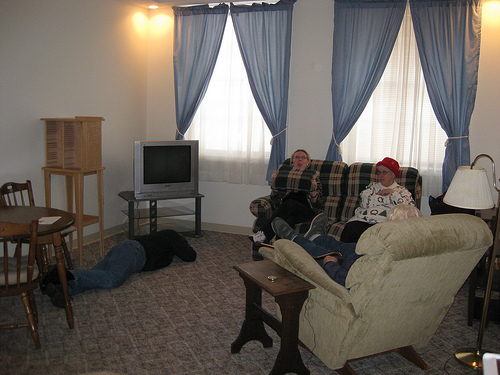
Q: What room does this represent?
A: It represents the living room.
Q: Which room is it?
A: It is a living room.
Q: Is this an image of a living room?
A: Yes, it is showing a living room.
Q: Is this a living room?
A: Yes, it is a living room.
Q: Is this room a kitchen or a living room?
A: It is a living room.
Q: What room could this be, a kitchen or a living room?
A: It is a living room.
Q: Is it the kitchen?
A: No, it is the living room.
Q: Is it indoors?
A: Yes, it is indoors.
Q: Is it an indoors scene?
A: Yes, it is indoors.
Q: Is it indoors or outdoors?
A: It is indoors.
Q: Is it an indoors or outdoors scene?
A: It is indoors.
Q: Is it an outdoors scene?
A: No, it is indoors.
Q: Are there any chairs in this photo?
A: Yes, there is a chair.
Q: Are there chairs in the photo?
A: Yes, there is a chair.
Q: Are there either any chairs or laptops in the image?
A: Yes, there is a chair.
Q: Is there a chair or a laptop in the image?
A: Yes, there is a chair.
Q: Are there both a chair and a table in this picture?
A: Yes, there are both a chair and a table.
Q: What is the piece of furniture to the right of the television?
A: The piece of furniture is a chair.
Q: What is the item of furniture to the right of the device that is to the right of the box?
A: The piece of furniture is a chair.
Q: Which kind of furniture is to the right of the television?
A: The piece of furniture is a chair.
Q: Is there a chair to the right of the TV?
A: Yes, there is a chair to the right of the TV.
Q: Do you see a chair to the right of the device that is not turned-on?
A: Yes, there is a chair to the right of the TV.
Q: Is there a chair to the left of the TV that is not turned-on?
A: No, the chair is to the right of the TV.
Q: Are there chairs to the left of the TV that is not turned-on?
A: No, the chair is to the right of the TV.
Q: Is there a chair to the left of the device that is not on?
A: No, the chair is to the right of the TV.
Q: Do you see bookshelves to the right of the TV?
A: No, there is a chair to the right of the TV.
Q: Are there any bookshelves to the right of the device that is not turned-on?
A: No, there is a chair to the right of the TV.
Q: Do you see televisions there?
A: Yes, there is a television.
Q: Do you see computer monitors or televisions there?
A: Yes, there is a television.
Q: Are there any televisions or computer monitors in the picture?
A: Yes, there is a television.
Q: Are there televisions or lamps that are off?
A: Yes, the television is off.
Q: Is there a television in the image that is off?
A: Yes, there is a television that is off.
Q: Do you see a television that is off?
A: Yes, there is a television that is off.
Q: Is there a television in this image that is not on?
A: Yes, there is a television that is off.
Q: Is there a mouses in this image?
A: No, there are no computer mousess.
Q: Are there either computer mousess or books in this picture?
A: No, there are no computer mousess or books.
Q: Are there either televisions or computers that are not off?
A: No, there is a television but it is off.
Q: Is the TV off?
A: Yes, the TV is off.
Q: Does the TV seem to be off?
A: Yes, the TV is off.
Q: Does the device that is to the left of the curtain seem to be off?
A: Yes, the TV is off.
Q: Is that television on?
A: No, the television is off.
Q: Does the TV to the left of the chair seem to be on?
A: No, the television is off.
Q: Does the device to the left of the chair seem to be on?
A: No, the television is off.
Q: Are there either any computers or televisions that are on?
A: No, there is a television but it is off.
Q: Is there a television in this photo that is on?
A: No, there is a television but it is off.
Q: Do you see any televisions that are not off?
A: No, there is a television but it is off.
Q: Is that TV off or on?
A: The TV is off.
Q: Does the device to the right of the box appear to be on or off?
A: The TV is off.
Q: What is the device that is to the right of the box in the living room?
A: The device is a television.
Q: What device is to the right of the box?
A: The device is a television.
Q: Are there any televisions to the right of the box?
A: Yes, there is a television to the right of the box.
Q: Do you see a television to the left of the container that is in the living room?
A: No, the television is to the right of the box.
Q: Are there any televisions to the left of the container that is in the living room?
A: No, the television is to the right of the box.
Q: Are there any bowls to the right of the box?
A: No, there is a television to the right of the box.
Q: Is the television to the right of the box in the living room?
A: Yes, the television is to the right of the box.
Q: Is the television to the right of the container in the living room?
A: Yes, the television is to the right of the box.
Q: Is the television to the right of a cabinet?
A: No, the television is to the right of the box.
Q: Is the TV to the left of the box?
A: No, the TV is to the right of the box.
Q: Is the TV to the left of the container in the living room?
A: No, the TV is to the right of the box.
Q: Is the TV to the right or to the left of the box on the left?
A: The TV is to the right of the box.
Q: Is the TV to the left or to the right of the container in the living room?
A: The TV is to the right of the box.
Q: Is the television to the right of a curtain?
A: No, the television is to the left of a curtain.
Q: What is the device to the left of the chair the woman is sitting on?
A: The device is a television.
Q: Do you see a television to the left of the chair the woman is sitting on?
A: Yes, there is a television to the left of the chair.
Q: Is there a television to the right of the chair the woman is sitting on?
A: No, the television is to the left of the chair.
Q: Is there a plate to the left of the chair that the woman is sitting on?
A: No, there is a television to the left of the chair.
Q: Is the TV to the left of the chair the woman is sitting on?
A: Yes, the TV is to the left of the chair.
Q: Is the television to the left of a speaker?
A: No, the television is to the left of the chair.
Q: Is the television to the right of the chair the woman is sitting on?
A: No, the television is to the left of the chair.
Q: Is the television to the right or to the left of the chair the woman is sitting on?
A: The television is to the left of the chair.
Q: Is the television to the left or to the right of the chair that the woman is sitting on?
A: The television is to the left of the chair.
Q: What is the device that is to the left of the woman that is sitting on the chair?
A: The device is a television.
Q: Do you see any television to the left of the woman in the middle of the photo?
A: Yes, there is a television to the left of the woman.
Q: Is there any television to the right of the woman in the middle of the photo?
A: No, the television is to the left of the woman.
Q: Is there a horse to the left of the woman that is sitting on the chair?
A: No, there is a television to the left of the woman.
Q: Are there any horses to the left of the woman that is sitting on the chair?
A: No, there is a television to the left of the woman.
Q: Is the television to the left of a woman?
A: Yes, the television is to the left of a woman.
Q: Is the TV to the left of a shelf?
A: No, the TV is to the left of a woman.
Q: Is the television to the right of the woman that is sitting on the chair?
A: No, the television is to the left of the woman.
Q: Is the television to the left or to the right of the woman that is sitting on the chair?
A: The television is to the left of the woman.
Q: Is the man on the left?
A: Yes, the man is on the left of the image.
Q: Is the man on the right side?
A: No, the man is on the left of the image.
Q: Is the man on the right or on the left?
A: The man is on the left of the image.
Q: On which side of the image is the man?
A: The man is on the left of the image.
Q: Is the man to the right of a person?
A: No, the man is to the left of a person.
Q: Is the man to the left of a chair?
A: No, the man is to the right of a chair.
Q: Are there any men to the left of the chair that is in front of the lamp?
A: Yes, there is a man to the left of the chair.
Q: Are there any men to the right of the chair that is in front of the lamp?
A: No, the man is to the left of the chair.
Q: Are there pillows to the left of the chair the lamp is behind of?
A: No, there is a man to the left of the chair.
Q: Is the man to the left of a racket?
A: No, the man is to the left of a chair.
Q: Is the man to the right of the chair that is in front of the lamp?
A: No, the man is to the left of the chair.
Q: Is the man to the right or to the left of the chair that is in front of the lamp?
A: The man is to the left of the chair.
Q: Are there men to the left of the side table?
A: Yes, there is a man to the left of the side table.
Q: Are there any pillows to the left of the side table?
A: No, there is a man to the left of the side table.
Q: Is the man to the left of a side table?
A: Yes, the man is to the left of a side table.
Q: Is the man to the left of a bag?
A: No, the man is to the left of a side table.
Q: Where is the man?
A: The man is on the floor.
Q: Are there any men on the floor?
A: Yes, there is a man on the floor.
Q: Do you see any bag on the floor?
A: No, there is a man on the floor.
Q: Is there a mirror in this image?
A: No, there are no mirrors.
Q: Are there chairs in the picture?
A: Yes, there is a chair.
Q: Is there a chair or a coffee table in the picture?
A: Yes, there is a chair.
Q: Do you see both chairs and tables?
A: Yes, there are both a chair and a table.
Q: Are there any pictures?
A: No, there are no pictures.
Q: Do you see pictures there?
A: No, there are no pictures.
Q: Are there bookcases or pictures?
A: No, there are no pictures or bookcases.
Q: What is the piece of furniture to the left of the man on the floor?
A: The piece of furniture is a chair.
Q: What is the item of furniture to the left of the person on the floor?
A: The piece of furniture is a chair.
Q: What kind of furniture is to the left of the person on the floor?
A: The piece of furniture is a chair.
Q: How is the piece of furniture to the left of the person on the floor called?
A: The piece of furniture is a chair.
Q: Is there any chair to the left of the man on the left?
A: Yes, there is a chair to the left of the man.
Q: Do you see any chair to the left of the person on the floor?
A: Yes, there is a chair to the left of the man.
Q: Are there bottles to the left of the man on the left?
A: No, there is a chair to the left of the man.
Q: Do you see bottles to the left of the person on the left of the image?
A: No, there is a chair to the left of the man.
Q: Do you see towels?
A: No, there are no towels.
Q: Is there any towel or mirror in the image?
A: No, there are no towels or mirrors.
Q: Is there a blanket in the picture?
A: No, there are no blankets.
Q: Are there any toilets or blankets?
A: No, there are no blankets or toilets.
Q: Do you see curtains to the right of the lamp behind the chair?
A: Yes, there is a curtain to the right of the lamp.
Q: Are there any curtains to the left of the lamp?
A: No, the curtain is to the right of the lamp.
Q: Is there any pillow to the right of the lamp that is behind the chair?
A: No, there is a curtain to the right of the lamp.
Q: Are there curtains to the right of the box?
A: Yes, there is a curtain to the right of the box.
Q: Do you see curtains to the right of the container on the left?
A: Yes, there is a curtain to the right of the box.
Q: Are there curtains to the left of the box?
A: No, the curtain is to the right of the box.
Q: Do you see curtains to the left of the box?
A: No, the curtain is to the right of the box.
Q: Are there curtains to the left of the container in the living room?
A: No, the curtain is to the right of the box.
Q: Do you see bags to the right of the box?
A: No, there is a curtain to the right of the box.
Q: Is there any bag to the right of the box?
A: No, there is a curtain to the right of the box.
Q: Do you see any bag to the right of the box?
A: No, there is a curtain to the right of the box.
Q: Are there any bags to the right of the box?
A: No, there is a curtain to the right of the box.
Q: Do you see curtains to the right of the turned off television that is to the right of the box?
A: Yes, there is a curtain to the right of the TV.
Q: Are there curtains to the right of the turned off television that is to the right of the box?
A: Yes, there is a curtain to the right of the TV.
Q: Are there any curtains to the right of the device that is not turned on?
A: Yes, there is a curtain to the right of the TV.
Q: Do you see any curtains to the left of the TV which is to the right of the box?
A: No, the curtain is to the right of the TV.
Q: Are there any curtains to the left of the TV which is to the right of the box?
A: No, the curtain is to the right of the TV.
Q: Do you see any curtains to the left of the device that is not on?
A: No, the curtain is to the right of the TV.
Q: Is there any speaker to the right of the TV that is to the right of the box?
A: No, there is a curtain to the right of the TV.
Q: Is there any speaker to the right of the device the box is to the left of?
A: No, there is a curtain to the right of the TV.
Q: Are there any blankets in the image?
A: No, there are no blankets.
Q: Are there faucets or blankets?
A: No, there are no blankets or faucets.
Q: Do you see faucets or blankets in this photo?
A: No, there are no blankets or faucets.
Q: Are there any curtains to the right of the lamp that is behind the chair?
A: Yes, there is a curtain to the right of the lamp.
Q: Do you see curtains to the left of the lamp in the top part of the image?
A: No, the curtain is to the right of the lamp.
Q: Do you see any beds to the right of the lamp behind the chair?
A: No, there is a curtain to the right of the lamp.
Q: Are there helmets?
A: No, there are no helmets.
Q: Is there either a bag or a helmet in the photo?
A: No, there are no helmets or bags.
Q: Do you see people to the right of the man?
A: Yes, there is a person to the right of the man.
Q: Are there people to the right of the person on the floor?
A: Yes, there is a person to the right of the man.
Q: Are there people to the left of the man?
A: No, the person is to the right of the man.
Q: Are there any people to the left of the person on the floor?
A: No, the person is to the right of the man.